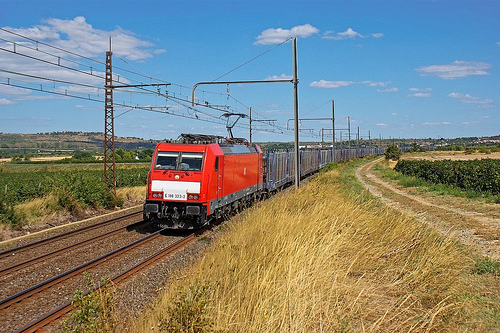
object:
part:
[144, 140, 202, 228]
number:
[170, 194, 174, 199]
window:
[155, 150, 203, 171]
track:
[0, 232, 182, 332]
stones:
[108, 258, 122, 273]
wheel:
[189, 220, 219, 235]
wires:
[0, 68, 148, 95]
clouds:
[250, 19, 386, 50]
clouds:
[0, 12, 166, 112]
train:
[139, 129, 411, 232]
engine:
[140, 130, 267, 230]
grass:
[214, 239, 242, 278]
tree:
[382, 144, 402, 162]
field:
[2, 158, 161, 203]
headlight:
[152, 192, 164, 199]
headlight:
[187, 193, 199, 201]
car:
[137, 140, 267, 232]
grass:
[257, 197, 290, 228]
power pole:
[96, 30, 120, 193]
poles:
[288, 34, 302, 194]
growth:
[394, 155, 484, 190]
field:
[207, 148, 484, 331]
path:
[352, 158, 497, 247]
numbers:
[179, 195, 183, 199]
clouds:
[420, 58, 492, 83]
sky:
[0, 0, 499, 135]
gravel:
[100, 235, 170, 268]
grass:
[157, 277, 196, 318]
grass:
[340, 307, 367, 331]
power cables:
[0, 83, 228, 127]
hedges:
[394, 156, 498, 199]